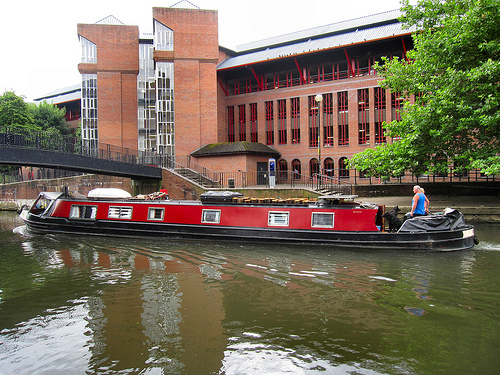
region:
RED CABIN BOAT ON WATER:
[13, 180, 485, 257]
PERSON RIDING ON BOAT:
[401, 183, 433, 217]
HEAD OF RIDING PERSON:
[408, 182, 426, 194]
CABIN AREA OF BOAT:
[17, 186, 52, 212]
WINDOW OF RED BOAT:
[195, 206, 225, 221]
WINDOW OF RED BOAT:
[101, 202, 136, 217]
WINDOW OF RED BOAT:
[65, 200, 100, 216]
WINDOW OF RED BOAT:
[143, 205, 170, 224]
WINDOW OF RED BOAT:
[262, 210, 295, 230]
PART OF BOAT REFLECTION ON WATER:
[151, 249, 205, 274]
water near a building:
[1, 209, 486, 374]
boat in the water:
[9, 174, 479, 264]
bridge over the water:
[3, 118, 167, 178]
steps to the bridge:
[169, 154, 217, 188]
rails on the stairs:
[173, 156, 218, 186]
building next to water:
[49, 14, 487, 176]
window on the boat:
[201, 215, 223, 227]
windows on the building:
[77, 36, 100, 137]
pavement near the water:
[378, 187, 495, 206]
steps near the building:
[298, 168, 343, 201]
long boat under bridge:
[15, 191, 463, 261]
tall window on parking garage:
[225, 102, 237, 142]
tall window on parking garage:
[238, 100, 247, 140]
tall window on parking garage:
[247, 96, 257, 150]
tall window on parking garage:
[262, 97, 274, 145]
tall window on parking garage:
[275, 100, 286, 143]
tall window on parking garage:
[285, 96, 301, 146]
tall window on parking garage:
[306, 92, 323, 149]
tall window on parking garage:
[318, 91, 339, 145]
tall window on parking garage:
[337, 89, 353, 153]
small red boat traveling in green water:
[16, 167, 499, 291]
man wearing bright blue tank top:
[403, 180, 427, 223]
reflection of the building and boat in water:
[16, 242, 299, 370]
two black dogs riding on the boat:
[382, 175, 399, 233]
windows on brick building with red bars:
[217, 89, 406, 159]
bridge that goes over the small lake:
[1, 120, 184, 216]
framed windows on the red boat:
[98, 202, 360, 244]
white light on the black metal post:
[310, 86, 325, 193]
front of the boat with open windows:
[19, 188, 75, 229]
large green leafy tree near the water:
[357, 0, 497, 218]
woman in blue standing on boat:
[409, 183, 429, 218]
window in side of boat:
[311, 210, 335, 227]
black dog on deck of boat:
[382, 211, 403, 230]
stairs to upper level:
[311, 187, 352, 199]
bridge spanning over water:
[0, 127, 160, 179]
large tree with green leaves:
[342, 0, 498, 180]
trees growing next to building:
[1, 88, 79, 180]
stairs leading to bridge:
[167, 163, 214, 188]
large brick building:
[0, 0, 497, 200]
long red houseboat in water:
[20, 185, 478, 252]